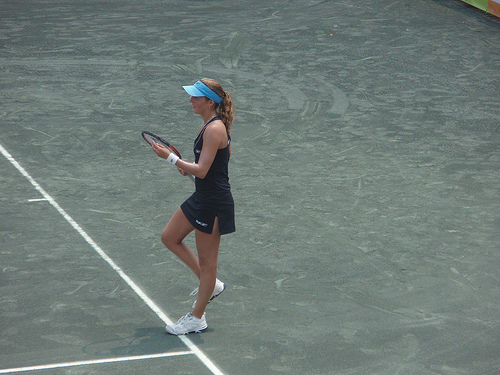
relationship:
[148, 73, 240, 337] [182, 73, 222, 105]
woman has visor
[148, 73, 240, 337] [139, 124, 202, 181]
woman has racket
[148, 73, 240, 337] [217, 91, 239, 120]
woman has ponytail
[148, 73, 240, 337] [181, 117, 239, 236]
woman wears dress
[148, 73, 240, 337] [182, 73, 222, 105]
woman wears visor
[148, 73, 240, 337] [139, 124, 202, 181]
woman holds racket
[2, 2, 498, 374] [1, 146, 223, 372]
court has lines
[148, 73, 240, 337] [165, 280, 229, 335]
woman has shoes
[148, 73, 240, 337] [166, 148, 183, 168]
woman wears wristband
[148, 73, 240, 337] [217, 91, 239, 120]
woman wears ponytail